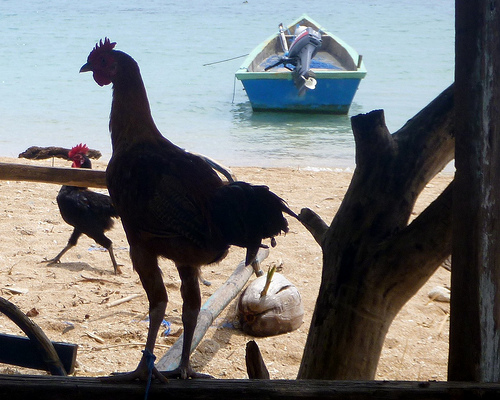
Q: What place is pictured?
A: It is a beach.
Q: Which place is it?
A: It is a beach.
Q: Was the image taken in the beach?
A: Yes, it was taken in the beach.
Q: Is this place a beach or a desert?
A: It is a beach.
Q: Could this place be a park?
A: No, it is a beach.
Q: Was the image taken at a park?
A: No, the picture was taken in a beach.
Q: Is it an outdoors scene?
A: Yes, it is outdoors.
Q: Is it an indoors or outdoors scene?
A: It is outdoors.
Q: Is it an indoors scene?
A: No, it is outdoors.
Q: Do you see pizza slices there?
A: No, there are no pizza slices.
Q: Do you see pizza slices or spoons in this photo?
A: No, there are no pizza slices or spoons.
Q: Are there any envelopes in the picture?
A: No, there are no envelopes.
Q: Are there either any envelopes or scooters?
A: No, there are no envelopes or scooters.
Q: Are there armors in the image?
A: No, there are no armors.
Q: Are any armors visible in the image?
A: No, there are no armors.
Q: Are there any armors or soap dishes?
A: No, there are no armors or soap dishes.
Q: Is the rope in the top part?
A: Yes, the rope is in the top of the image.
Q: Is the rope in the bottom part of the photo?
A: No, the rope is in the top of the image.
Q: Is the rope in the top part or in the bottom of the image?
A: The rope is in the top of the image.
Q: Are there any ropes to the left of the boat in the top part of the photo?
A: Yes, there is a rope to the left of the boat.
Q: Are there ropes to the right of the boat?
A: No, the rope is to the left of the boat.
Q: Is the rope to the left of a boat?
A: Yes, the rope is to the left of a boat.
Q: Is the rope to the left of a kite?
A: No, the rope is to the left of a boat.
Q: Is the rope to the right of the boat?
A: No, the rope is to the left of the boat.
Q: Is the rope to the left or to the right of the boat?
A: The rope is to the left of the boat.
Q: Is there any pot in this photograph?
A: No, there are no pots.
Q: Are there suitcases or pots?
A: No, there are no pots or suitcases.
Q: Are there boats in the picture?
A: Yes, there is a boat.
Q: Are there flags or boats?
A: Yes, there is a boat.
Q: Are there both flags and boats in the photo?
A: No, there is a boat but no flags.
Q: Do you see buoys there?
A: No, there are no buoys.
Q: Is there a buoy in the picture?
A: No, there are no buoys.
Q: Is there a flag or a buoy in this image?
A: No, there are no buoys or flags.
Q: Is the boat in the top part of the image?
A: Yes, the boat is in the top of the image.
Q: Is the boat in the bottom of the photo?
A: No, the boat is in the top of the image.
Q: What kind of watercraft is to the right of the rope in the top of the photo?
A: The watercraft is a boat.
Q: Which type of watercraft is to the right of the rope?
A: The watercraft is a boat.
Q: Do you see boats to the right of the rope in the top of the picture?
A: Yes, there is a boat to the right of the rope.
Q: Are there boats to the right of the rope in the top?
A: Yes, there is a boat to the right of the rope.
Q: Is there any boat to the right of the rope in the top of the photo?
A: Yes, there is a boat to the right of the rope.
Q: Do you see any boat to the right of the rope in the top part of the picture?
A: Yes, there is a boat to the right of the rope.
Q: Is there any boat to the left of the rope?
A: No, the boat is to the right of the rope.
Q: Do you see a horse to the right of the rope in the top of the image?
A: No, there is a boat to the right of the rope.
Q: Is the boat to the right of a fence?
A: No, the boat is to the right of a rope.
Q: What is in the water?
A: The boat is in the water.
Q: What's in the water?
A: The boat is in the water.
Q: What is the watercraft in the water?
A: The watercraft is a boat.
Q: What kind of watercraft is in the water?
A: The watercraft is a boat.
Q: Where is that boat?
A: The boat is in the water.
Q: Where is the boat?
A: The boat is in the water.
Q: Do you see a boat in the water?
A: Yes, there is a boat in the water.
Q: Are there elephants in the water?
A: No, there is a boat in the water.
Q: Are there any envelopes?
A: No, there are no envelopes.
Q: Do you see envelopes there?
A: No, there are no envelopes.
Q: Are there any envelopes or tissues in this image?
A: No, there are no envelopes or tissues.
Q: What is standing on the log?
A: The chicken is standing on the log.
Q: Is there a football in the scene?
A: No, there are no footballs.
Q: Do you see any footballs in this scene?
A: No, there are no footballs.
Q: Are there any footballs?
A: No, there are no footballs.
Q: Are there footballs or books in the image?
A: No, there are no footballs or books.